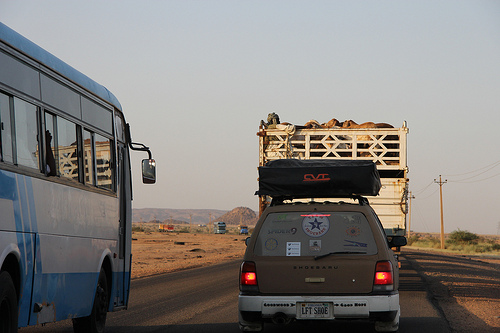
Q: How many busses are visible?
A: One.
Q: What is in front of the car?
A: A truck.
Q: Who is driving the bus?
A: The driver.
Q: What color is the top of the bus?
A: Blue.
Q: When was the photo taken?
A: Daytime.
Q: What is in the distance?
A: The horizon.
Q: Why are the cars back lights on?
A: It is braking.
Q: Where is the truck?
A: In front of the car.